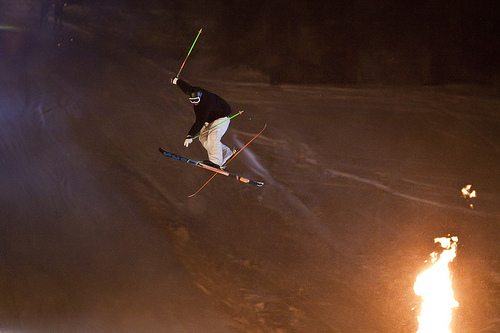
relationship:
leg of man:
[204, 118, 230, 165] [153, 57, 282, 200]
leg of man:
[197, 127, 230, 164] [153, 57, 282, 200]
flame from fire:
[391, 200, 469, 318] [411, 182, 479, 331]